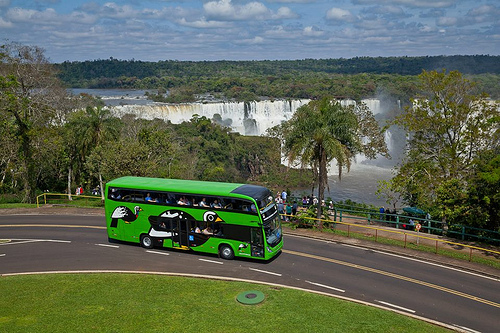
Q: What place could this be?
A: It is a lake.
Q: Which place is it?
A: It is a lake.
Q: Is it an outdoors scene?
A: Yes, it is outdoors.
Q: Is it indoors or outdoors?
A: It is outdoors.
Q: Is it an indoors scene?
A: No, it is outdoors.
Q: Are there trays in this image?
A: No, there are no trays.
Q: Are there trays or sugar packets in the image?
A: No, there are no trays or sugar packets.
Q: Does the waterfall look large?
A: Yes, the waterfall is large.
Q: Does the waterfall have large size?
A: Yes, the waterfall is large.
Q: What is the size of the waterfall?
A: The waterfall is large.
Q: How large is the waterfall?
A: The waterfall is large.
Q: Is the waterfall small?
A: No, the waterfall is large.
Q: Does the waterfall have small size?
A: No, the waterfall is large.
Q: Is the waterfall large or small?
A: The waterfall is large.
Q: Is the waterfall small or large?
A: The waterfall is large.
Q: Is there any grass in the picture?
A: Yes, there is grass.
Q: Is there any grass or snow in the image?
A: Yes, there is grass.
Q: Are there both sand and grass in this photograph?
A: No, there is grass but no sand.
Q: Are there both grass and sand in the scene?
A: No, there is grass but no sand.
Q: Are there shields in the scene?
A: No, there are no shields.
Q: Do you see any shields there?
A: No, there are no shields.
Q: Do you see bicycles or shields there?
A: No, there are no shields or bicycles.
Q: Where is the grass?
A: The grass is on the street.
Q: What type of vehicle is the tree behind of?
A: The tree is behind the bus.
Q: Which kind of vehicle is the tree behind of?
A: The tree is behind the bus.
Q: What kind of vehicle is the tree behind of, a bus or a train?
A: The tree is behind a bus.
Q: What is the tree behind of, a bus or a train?
A: The tree is behind a bus.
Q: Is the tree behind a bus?
A: Yes, the tree is behind a bus.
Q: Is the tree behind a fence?
A: No, the tree is behind a bus.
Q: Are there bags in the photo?
A: No, there are no bags.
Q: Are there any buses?
A: Yes, there is a bus.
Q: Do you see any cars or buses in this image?
A: Yes, there is a bus.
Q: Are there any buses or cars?
A: Yes, there is a bus.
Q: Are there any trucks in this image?
A: No, there are no trucks.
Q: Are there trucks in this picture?
A: No, there are no trucks.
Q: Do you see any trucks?
A: No, there are no trucks.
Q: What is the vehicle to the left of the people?
A: The vehicle is a bus.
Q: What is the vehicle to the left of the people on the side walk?
A: The vehicle is a bus.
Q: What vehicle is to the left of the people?
A: The vehicle is a bus.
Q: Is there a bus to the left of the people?
A: Yes, there is a bus to the left of the people.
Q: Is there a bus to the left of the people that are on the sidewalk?
A: Yes, there is a bus to the left of the people.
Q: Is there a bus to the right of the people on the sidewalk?
A: No, the bus is to the left of the people.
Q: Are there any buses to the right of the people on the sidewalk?
A: No, the bus is to the left of the people.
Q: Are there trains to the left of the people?
A: No, there is a bus to the left of the people.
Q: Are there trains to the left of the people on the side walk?
A: No, there is a bus to the left of the people.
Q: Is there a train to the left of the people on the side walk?
A: No, there is a bus to the left of the people.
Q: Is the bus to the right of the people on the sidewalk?
A: No, the bus is to the left of the people.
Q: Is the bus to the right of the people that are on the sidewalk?
A: No, the bus is to the left of the people.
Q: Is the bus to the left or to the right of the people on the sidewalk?
A: The bus is to the left of the people.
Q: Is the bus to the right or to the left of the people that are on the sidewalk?
A: The bus is to the left of the people.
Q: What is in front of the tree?
A: The bus is in front of the tree.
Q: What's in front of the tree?
A: The bus is in front of the tree.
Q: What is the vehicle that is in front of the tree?
A: The vehicle is a bus.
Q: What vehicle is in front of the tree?
A: The vehicle is a bus.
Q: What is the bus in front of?
A: The bus is in front of the tree.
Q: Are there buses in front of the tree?
A: Yes, there is a bus in front of the tree.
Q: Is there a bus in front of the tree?
A: Yes, there is a bus in front of the tree.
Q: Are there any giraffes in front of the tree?
A: No, there is a bus in front of the tree.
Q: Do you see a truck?
A: No, there are no trucks.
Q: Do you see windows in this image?
A: Yes, there is a window.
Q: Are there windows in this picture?
A: Yes, there is a window.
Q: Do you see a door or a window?
A: Yes, there is a window.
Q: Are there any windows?
A: Yes, there are windows.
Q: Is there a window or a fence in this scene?
A: Yes, there are windows.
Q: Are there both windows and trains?
A: No, there are windows but no trains.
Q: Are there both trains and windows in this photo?
A: No, there are windows but no trains.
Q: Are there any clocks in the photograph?
A: No, there are no clocks.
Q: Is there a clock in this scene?
A: No, there are no clocks.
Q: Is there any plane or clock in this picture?
A: No, there are no clocks or airplanes.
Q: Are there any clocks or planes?
A: No, there are no clocks or planes.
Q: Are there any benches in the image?
A: No, there are no benches.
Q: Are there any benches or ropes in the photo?
A: No, there are no benches or ropes.